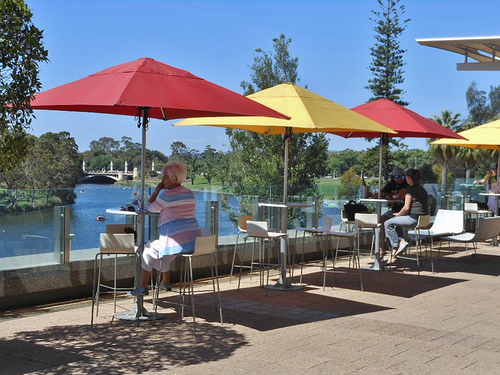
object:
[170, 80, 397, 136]
umbrella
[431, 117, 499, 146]
umbrella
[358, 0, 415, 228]
tree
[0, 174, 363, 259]
water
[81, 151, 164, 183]
bridge